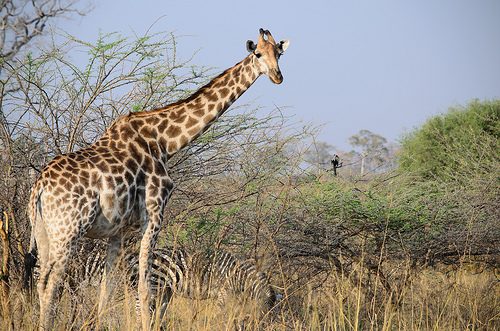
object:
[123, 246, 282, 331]
zebra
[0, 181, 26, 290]
bush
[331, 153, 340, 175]
bird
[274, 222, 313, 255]
limb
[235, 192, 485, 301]
brush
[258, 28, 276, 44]
horns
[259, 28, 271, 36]
black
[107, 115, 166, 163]
shoulders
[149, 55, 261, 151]
neck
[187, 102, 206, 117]
spots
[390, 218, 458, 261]
limbs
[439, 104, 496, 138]
leaves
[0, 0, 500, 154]
sky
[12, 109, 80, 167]
limbs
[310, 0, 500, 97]
haze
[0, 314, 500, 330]
grass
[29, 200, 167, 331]
legs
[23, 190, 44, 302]
tail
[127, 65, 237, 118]
mane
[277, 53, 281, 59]
eyes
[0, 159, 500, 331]
field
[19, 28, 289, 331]
animals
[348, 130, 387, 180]
tree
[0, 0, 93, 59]
branches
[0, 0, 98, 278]
tree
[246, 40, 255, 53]
ear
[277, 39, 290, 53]
ear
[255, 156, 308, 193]
branch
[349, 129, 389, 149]
branches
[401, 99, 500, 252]
bush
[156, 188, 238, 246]
bush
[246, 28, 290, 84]
head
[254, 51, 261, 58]
eye